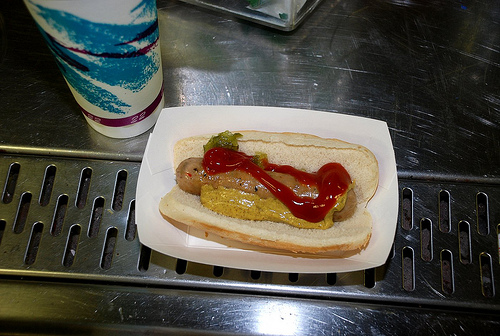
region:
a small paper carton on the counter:
[118, 93, 423, 285]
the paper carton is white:
[110, 94, 407, 281]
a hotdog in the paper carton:
[93, 98, 411, 275]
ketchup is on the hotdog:
[177, 124, 354, 234]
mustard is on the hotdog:
[195, 166, 355, 233]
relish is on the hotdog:
[182, 120, 252, 159]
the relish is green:
[178, 115, 260, 170]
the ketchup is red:
[250, 155, 356, 206]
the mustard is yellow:
[185, 179, 292, 229]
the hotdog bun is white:
[143, 120, 381, 256]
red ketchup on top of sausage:
[198, 150, 345, 199]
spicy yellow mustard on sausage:
[198, 183, 260, 228]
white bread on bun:
[156, 125, 382, 260]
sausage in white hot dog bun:
[171, 153, 361, 225]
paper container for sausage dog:
[128, 101, 403, 276]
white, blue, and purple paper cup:
[20, 0, 168, 143]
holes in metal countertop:
[428, 185, 496, 262]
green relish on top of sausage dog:
[198, 125, 243, 155]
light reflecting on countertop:
[171, 61, 244, 100]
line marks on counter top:
[403, 95, 490, 163]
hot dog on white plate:
[160, 134, 386, 256]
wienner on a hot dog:
[175, 153, 355, 226]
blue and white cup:
[18, 2, 162, 138]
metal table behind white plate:
[0, 8, 492, 326]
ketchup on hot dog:
[203, 147, 348, 220]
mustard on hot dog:
[203, 176, 343, 230]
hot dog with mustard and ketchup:
[166, 129, 382, 256]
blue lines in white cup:
[38, 1, 164, 109]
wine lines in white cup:
[50, 16, 164, 127]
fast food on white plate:
[158, 130, 380, 259]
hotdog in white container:
[130, 81, 412, 280]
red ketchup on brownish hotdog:
[205, 133, 334, 224]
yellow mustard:
[192, 182, 342, 232]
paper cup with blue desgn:
[31, 7, 168, 143]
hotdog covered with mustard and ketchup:
[170, 156, 343, 206]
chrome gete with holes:
[26, 156, 122, 270]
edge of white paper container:
[132, 111, 162, 261]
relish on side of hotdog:
[201, 124, 262, 163]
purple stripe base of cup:
[69, 96, 175, 145]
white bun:
[157, 198, 378, 265]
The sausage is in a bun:
[157, 125, 380, 259]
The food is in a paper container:
[134, 102, 404, 276]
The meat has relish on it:
[133, 104, 400, 274]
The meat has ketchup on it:
[135, 102, 394, 269]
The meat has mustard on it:
[132, 100, 400, 277]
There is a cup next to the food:
[18, 4, 164, 135]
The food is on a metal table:
[131, 102, 401, 274]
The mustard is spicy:
[191, 181, 361, 230]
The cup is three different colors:
[26, 4, 164, 142]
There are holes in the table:
[0, 142, 498, 312]